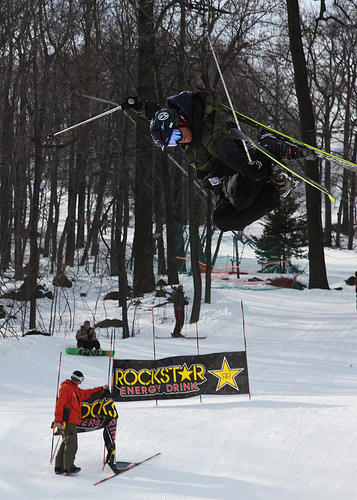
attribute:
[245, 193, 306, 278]
tree — small